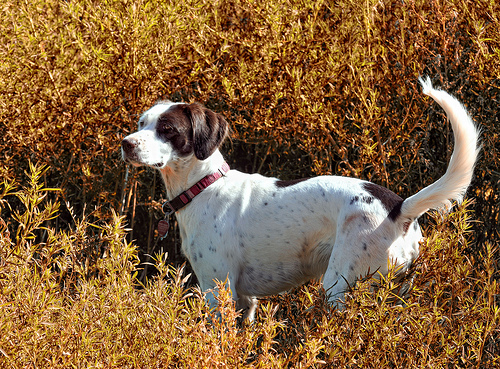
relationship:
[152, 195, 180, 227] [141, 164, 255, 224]
tags are attached to collar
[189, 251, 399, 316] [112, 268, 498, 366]
legs are hidden in grass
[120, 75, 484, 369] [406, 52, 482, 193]
dog has tail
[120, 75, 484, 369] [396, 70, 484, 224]
dog has tail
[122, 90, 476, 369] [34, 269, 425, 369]
dog in a field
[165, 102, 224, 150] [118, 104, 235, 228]
spot on dogs head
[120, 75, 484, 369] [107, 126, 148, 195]
dog wet black nose